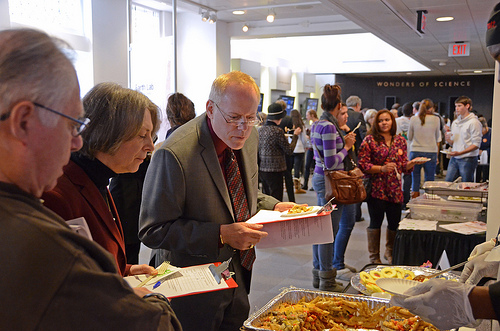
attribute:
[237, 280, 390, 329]
tray — silver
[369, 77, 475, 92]
sign — wonders of science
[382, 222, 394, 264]
boot — brown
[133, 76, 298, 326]
guy — older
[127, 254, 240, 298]
clipboard — orange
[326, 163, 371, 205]
leather bag — brown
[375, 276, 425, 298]
paper plate — white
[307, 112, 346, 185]
sweater — purple, gray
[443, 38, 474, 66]
exit — red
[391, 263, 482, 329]
glove — white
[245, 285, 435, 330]
tray — metal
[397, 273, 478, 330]
glove — rubber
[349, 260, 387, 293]
circles — pineapple